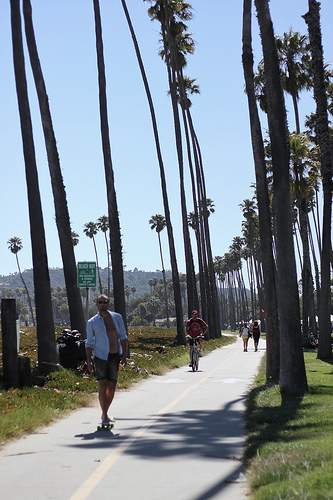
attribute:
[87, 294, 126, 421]
man — biking, skateboarding, barefoot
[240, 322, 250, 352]
woman — walking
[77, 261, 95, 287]
sign — green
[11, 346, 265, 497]
road — two lane, bike path, large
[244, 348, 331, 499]
grass — green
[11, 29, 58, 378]
tree — large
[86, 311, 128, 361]
shirt — un-buttoned, blue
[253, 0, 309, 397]
tree — large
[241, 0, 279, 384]
tree — large